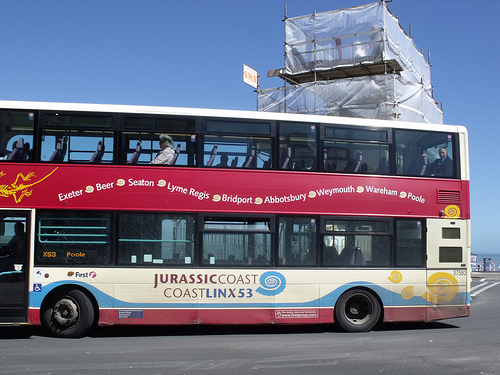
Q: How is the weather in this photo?
A: It is clear.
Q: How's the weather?
A: It is clear.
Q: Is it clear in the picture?
A: Yes, it is clear.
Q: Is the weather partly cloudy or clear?
A: It is clear.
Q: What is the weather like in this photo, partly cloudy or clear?
A: It is clear.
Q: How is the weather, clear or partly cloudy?
A: It is clear.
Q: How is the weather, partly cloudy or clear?
A: It is clear.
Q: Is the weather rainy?
A: No, it is clear.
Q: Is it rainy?
A: No, it is clear.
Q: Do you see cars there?
A: No, there are no cars.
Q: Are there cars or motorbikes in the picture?
A: No, there are no cars or motorbikes.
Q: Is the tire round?
A: Yes, the tire is round.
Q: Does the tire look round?
A: Yes, the tire is round.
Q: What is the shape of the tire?
A: The tire is round.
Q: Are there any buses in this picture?
A: Yes, there is a bus.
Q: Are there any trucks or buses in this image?
A: Yes, there is a bus.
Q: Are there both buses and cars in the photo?
A: No, there is a bus but no cars.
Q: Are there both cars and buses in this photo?
A: No, there is a bus but no cars.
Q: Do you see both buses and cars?
A: No, there is a bus but no cars.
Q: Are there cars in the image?
A: No, there are no cars.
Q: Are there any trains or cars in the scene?
A: No, there are no cars or trains.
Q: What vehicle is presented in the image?
A: The vehicle is a bus.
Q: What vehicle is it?
A: The vehicle is a bus.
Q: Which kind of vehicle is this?
A: This is a bus.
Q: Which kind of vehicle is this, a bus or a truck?
A: This is a bus.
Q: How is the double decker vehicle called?
A: The vehicle is a bus.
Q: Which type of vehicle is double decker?
A: The vehicle is a bus.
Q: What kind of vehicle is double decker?
A: The vehicle is a bus.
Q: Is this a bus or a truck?
A: This is a bus.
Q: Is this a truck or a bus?
A: This is a bus.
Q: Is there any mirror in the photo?
A: No, there are no mirrors.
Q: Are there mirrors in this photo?
A: No, there are no mirrors.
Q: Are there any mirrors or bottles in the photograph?
A: No, there are no mirrors or bottles.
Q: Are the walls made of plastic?
A: Yes, the walls are made of plastic.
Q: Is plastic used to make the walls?
A: Yes, the walls are made of plastic.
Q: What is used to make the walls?
A: The walls are made of plastic.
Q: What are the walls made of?
A: The walls are made of plastic.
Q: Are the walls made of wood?
A: No, the walls are made of plastic.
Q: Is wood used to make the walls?
A: No, the walls are made of plastic.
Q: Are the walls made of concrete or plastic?
A: The walls are made of plastic.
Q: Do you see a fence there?
A: No, there are no fences.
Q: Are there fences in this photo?
A: No, there are no fences.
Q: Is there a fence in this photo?
A: No, there are no fences.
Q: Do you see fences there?
A: No, there are no fences.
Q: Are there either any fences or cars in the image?
A: No, there are no fences or cars.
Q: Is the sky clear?
A: Yes, the sky is clear.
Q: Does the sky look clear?
A: Yes, the sky is clear.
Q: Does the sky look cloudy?
A: No, the sky is clear.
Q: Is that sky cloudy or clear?
A: The sky is clear.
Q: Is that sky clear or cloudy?
A: The sky is clear.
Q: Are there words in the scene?
A: Yes, there are words.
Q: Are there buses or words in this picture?
A: Yes, there are words.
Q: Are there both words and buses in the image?
A: Yes, there are both words and a bus.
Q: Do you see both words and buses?
A: Yes, there are both words and a bus.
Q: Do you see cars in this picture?
A: No, there are no cars.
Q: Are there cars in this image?
A: No, there are no cars.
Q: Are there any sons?
A: No, there are no sons.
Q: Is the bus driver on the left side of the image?
A: Yes, the driver is on the left of the image.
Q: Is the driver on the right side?
A: No, the driver is on the left of the image.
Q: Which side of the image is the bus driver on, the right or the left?
A: The driver is on the left of the image.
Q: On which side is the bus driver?
A: The driver is on the left of the image.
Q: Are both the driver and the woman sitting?
A: Yes, both the driver and the woman are sitting.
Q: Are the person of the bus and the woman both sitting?
A: Yes, both the driver and the woman are sitting.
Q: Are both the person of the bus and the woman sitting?
A: Yes, both the driver and the woman are sitting.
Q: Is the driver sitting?
A: Yes, the driver is sitting.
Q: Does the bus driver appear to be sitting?
A: Yes, the driver is sitting.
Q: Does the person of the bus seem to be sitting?
A: Yes, the driver is sitting.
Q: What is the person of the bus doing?
A: The driver is sitting.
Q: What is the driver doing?
A: The driver is sitting.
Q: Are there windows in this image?
A: Yes, there are windows.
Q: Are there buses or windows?
A: Yes, there are windows.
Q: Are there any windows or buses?
A: Yes, there are windows.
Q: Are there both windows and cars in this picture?
A: No, there are windows but no cars.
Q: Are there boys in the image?
A: No, there are no boys.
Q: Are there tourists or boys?
A: No, there are no boys or tourists.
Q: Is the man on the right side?
A: Yes, the man is on the right of the image.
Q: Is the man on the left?
A: No, the man is on the right of the image.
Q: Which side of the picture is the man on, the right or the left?
A: The man is on the right of the image.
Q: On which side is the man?
A: The man is on the right of the image.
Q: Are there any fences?
A: No, there are no fences.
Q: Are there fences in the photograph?
A: No, there are no fences.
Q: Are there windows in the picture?
A: Yes, there are windows.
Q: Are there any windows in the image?
A: Yes, there are windows.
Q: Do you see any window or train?
A: Yes, there are windows.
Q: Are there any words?
A: Yes, there are words.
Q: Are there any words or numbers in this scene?
A: Yes, there are words.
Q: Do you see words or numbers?
A: Yes, there are words.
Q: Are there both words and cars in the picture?
A: No, there are words but no cars.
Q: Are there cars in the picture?
A: No, there are no cars.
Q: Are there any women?
A: Yes, there is a woman.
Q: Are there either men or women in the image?
A: Yes, there is a woman.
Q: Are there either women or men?
A: Yes, there is a woman.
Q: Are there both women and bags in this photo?
A: No, there is a woman but no bags.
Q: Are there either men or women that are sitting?
A: Yes, the woman is sitting.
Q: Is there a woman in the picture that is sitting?
A: Yes, there is a woman that is sitting.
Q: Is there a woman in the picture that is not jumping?
A: Yes, there is a woman that is sitting.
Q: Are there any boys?
A: No, there are no boys.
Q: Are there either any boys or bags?
A: No, there are no boys or bags.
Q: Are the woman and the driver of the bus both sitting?
A: Yes, both the woman and the driver are sitting.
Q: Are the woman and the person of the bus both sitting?
A: Yes, both the woman and the driver are sitting.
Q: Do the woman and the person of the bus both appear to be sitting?
A: Yes, both the woman and the driver are sitting.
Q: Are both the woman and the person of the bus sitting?
A: Yes, both the woman and the driver are sitting.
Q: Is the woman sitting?
A: Yes, the woman is sitting.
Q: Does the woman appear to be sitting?
A: Yes, the woman is sitting.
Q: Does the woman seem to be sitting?
A: Yes, the woman is sitting.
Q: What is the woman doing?
A: The woman is sitting.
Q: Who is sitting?
A: The woman is sitting.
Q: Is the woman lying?
A: No, the woman is sitting.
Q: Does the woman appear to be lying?
A: No, the woman is sitting.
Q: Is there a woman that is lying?
A: No, there is a woman but she is sitting.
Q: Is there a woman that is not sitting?
A: No, there is a woman but she is sitting.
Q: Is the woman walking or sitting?
A: The woman is sitting.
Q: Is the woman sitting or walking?
A: The woman is sitting.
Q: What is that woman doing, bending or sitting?
A: The woman is sitting.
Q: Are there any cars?
A: No, there are no cars.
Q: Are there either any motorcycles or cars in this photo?
A: No, there are no cars or motorcycles.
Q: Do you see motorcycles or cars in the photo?
A: No, there are no cars or motorcycles.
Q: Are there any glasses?
A: No, there are no glasses.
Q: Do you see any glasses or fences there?
A: No, there are no glasses or fences.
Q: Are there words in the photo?
A: Yes, there are words.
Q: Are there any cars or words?
A: Yes, there are words.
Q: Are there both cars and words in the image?
A: No, there are words but no cars.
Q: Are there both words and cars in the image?
A: No, there are words but no cars.